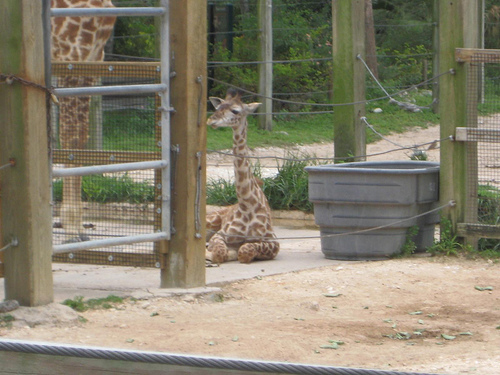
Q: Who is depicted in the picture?
A: A giraffe.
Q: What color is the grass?
A: Green.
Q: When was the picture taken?
A: During the day.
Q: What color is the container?
A: Gray.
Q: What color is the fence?
A: Silver.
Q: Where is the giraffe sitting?
A: On the ground.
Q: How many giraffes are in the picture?
A: Two.